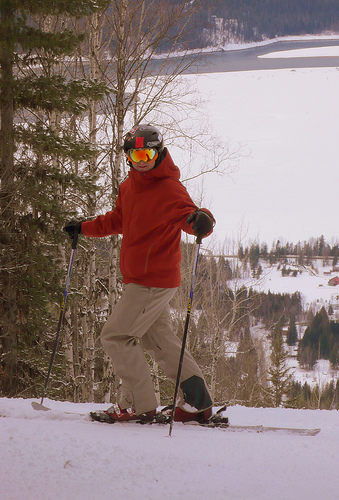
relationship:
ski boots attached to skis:
[104, 395, 207, 422] [112, 405, 241, 427]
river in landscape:
[3, 30, 336, 90] [2, 2, 335, 498]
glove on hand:
[183, 206, 215, 247] [184, 206, 215, 245]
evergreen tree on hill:
[0, 2, 110, 402] [0, 397, 337, 498]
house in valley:
[323, 271, 337, 288] [233, 257, 337, 317]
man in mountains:
[61, 120, 217, 425] [6, 26, 333, 498]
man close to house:
[61, 120, 217, 425] [327, 274, 338, 289]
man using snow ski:
[61, 120, 217, 425] [162, 410, 320, 437]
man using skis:
[61, 120, 217, 425] [182, 414, 321, 436]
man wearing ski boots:
[61, 120, 217, 425] [160, 394, 213, 426]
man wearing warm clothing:
[61, 120, 217, 425] [112, 142, 165, 167]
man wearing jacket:
[61, 120, 217, 425] [80, 148, 216, 288]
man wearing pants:
[61, 120, 217, 425] [95, 277, 214, 415]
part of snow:
[296, 199, 323, 228] [117, 69, 337, 295]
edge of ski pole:
[157, 393, 189, 439] [165, 225, 203, 437]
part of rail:
[42, 297, 74, 404] [36, 203, 57, 421]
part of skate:
[130, 406, 170, 427] [79, 395, 217, 420]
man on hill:
[61, 120, 217, 425] [0, 397, 338, 499]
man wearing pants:
[61, 120, 217, 425] [99, 279, 214, 409]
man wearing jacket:
[61, 120, 217, 425] [80, 156, 195, 288]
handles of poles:
[59, 219, 213, 251] [175, 242, 277, 455]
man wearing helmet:
[61, 120, 217, 425] [121, 123, 163, 172]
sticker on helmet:
[131, 135, 146, 149] [122, 119, 164, 158]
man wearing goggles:
[98, 111, 217, 413] [127, 144, 157, 162]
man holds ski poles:
[61, 120, 217, 425] [38, 233, 201, 436]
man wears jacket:
[61, 120, 217, 425] [80, 148, 216, 288]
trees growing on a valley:
[228, 254, 325, 430] [158, 256, 338, 412]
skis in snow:
[30, 396, 322, 437] [176, 447, 243, 473]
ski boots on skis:
[97, 393, 214, 428] [23, 386, 338, 436]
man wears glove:
[61, 120, 217, 425] [63, 217, 82, 239]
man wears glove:
[61, 120, 217, 425] [185, 208, 215, 241]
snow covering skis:
[2, 394, 338, 499] [2, 401, 321, 436]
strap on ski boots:
[111, 398, 121, 416] [105, 391, 158, 426]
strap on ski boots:
[120, 399, 136, 418] [105, 391, 158, 426]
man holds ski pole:
[61, 120, 217, 425] [31, 242, 82, 412]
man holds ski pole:
[61, 120, 217, 425] [165, 232, 209, 439]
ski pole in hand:
[31, 242, 82, 412] [188, 206, 215, 238]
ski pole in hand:
[165, 232, 209, 439] [60, 210, 84, 251]